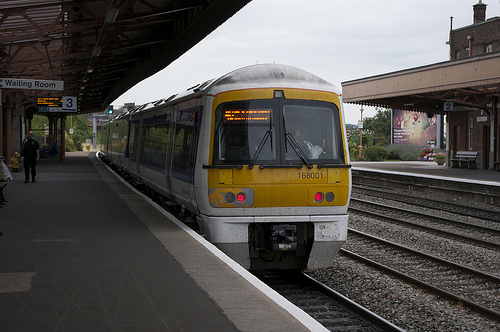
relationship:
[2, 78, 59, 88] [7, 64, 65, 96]
letters on sign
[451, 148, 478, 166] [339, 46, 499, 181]
bench next to train station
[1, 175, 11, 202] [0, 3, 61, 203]
bench next to train station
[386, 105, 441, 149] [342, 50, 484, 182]
poster next to station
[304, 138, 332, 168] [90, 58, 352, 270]
bag inside train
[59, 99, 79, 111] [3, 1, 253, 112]
sign hanging from roof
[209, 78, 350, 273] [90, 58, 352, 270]
front on train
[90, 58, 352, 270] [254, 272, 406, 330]
train on tracks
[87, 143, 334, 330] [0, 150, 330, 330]
curb of platform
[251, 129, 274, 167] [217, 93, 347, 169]
windshield wiper on train windshield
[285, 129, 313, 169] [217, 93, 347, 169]
windshield wiper on train windshield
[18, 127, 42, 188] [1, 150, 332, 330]
man standing on train platform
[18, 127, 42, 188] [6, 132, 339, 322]
man standing on platform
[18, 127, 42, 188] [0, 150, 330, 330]
man standing on platform